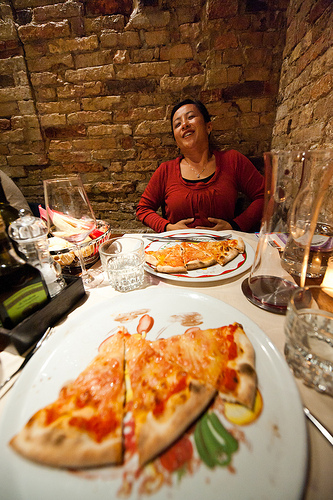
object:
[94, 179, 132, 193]
brick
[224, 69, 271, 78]
brick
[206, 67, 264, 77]
brick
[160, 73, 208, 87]
brick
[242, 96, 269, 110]
brick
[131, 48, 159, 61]
brick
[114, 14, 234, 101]
wall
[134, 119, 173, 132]
brick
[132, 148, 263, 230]
shirt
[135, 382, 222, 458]
crust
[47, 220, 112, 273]
basket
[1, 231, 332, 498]
table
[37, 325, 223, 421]
cheese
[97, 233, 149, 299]
crystal glass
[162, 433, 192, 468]
pepperoni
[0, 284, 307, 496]
plate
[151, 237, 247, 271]
pizza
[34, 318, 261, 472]
pizza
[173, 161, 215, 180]
jewelry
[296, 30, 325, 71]
brick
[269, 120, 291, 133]
brick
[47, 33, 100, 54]
brick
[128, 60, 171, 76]
brick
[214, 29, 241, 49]
brick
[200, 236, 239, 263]
pizza slice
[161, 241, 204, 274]
pizza slice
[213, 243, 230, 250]
toppings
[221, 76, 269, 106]
brick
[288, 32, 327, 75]
brick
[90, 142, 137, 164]
brick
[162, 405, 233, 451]
leaf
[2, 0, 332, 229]
brick wall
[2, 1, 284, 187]
brick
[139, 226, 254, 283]
plate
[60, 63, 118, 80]
brick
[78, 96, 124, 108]
brick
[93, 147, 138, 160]
brick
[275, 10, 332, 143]
brick wall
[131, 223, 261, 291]
plate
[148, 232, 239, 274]
pizza slices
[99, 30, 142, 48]
brick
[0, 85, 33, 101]
brick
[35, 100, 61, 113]
brick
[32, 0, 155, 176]
wall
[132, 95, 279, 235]
woman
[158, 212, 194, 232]
hands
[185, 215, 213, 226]
stomach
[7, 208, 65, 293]
shaker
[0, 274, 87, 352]
basket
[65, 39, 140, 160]
bricks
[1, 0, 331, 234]
building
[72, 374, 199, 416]
toppings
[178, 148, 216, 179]
neck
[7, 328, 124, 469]
pizza slice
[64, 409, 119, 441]
topping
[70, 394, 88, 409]
topping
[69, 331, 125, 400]
topping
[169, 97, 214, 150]
head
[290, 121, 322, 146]
brick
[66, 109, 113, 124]
brick